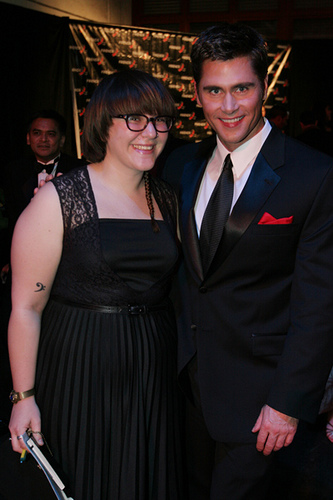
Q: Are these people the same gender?
A: No, they are both male and female.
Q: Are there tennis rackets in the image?
A: No, there are no tennis rackets.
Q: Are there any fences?
A: No, there are no fences.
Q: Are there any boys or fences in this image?
A: No, there are no fences or boys.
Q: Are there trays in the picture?
A: No, there are no trays.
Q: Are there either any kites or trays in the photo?
A: No, there are no trays or kites.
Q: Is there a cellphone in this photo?
A: No, there are no cell phones.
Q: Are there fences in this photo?
A: No, there are no fences.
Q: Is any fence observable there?
A: No, there are no fences.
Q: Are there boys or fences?
A: No, there are no fences or boys.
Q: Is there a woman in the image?
A: Yes, there is a woman.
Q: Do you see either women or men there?
A: Yes, there is a woman.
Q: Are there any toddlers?
A: No, there are no toddlers.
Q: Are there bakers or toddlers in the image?
A: No, there are no toddlers or bakers.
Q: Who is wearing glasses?
A: The woman is wearing glasses.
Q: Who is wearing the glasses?
A: The woman is wearing glasses.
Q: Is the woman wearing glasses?
A: Yes, the woman is wearing glasses.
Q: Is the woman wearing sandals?
A: No, the woman is wearing glasses.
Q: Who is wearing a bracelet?
A: The woman is wearing a bracelet.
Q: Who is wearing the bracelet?
A: The woman is wearing a bracelet.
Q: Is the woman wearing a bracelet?
A: Yes, the woman is wearing a bracelet.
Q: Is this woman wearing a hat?
A: No, the woman is wearing a bracelet.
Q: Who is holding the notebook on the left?
A: The woman is holding the notebook.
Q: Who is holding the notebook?
A: The woman is holding the notebook.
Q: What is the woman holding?
A: The woman is holding the notebook.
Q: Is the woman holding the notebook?
A: Yes, the woman is holding the notebook.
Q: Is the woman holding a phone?
A: No, the woman is holding the notebook.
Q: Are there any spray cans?
A: No, there are no spray cans.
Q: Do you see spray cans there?
A: No, there are no spray cans.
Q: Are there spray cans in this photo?
A: No, there are no spray cans.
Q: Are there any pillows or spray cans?
A: No, there are no spray cans or pillows.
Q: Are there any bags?
A: No, there are no bags.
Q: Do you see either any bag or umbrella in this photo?
A: No, there are no bags or umbrellas.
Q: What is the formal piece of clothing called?
A: The clothing item is a dress.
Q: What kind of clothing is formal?
A: The clothing is a dress.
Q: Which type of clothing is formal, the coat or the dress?
A: The dress is formal.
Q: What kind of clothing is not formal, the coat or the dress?
A: The coat is not formal.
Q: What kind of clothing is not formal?
A: The clothing is a coat.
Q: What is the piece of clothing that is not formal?
A: The clothing item is a coat.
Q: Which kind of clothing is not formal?
A: The clothing is a coat.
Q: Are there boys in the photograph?
A: No, there are no boys.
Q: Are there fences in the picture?
A: No, there are no fences.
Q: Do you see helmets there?
A: No, there are no helmets.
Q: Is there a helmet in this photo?
A: No, there are no helmets.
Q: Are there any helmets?
A: No, there are no helmets.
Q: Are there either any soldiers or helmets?
A: No, there are no helmets or soldiers.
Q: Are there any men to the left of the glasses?
A: Yes, there is a man to the left of the glasses.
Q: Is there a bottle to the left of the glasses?
A: No, there is a man to the left of the glasses.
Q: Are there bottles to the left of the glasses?
A: No, there is a man to the left of the glasses.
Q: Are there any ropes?
A: No, there are no ropes.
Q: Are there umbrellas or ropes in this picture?
A: No, there are no ropes or umbrellas.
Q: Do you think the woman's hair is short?
A: Yes, the hair is short.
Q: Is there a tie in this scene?
A: Yes, there is a tie.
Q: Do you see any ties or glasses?
A: Yes, there is a tie.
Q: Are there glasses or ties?
A: Yes, there is a tie.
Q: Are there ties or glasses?
A: Yes, there is a tie.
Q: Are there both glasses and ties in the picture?
A: Yes, there are both a tie and glasses.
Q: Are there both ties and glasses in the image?
A: Yes, there are both a tie and glasses.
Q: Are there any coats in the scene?
A: Yes, there is a coat.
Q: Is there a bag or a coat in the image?
A: Yes, there is a coat.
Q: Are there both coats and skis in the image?
A: No, there is a coat but no skis.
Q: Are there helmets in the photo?
A: No, there are no helmets.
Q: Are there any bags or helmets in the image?
A: No, there are no helmets or bags.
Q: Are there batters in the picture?
A: No, there are no batters.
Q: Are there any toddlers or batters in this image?
A: No, there are no batters or toddlers.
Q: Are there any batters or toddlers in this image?
A: No, there are no batters or toddlers.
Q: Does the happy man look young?
A: Yes, the man is young.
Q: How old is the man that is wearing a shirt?
A: The man is young.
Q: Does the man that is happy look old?
A: No, the man is young.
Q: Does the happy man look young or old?
A: The man is young.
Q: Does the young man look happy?
A: Yes, the man is happy.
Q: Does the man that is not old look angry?
A: No, the man is happy.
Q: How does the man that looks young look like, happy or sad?
A: The man is happy.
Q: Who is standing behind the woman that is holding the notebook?
A: The man is standing behind the woman.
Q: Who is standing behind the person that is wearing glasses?
A: The man is standing behind the woman.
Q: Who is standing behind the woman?
A: The man is standing behind the woman.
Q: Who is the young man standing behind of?
A: The man is standing behind the woman.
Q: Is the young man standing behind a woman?
A: Yes, the man is standing behind a woman.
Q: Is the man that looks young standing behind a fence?
A: No, the man is standing behind a woman.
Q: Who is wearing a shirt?
A: The man is wearing a shirt.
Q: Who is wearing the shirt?
A: The man is wearing a shirt.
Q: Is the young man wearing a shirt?
A: Yes, the man is wearing a shirt.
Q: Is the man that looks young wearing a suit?
A: No, the man is wearing a shirt.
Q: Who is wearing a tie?
A: The man is wearing a tie.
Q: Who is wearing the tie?
A: The man is wearing a tie.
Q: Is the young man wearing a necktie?
A: Yes, the man is wearing a necktie.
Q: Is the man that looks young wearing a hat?
A: No, the man is wearing a necktie.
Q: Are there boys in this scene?
A: No, there are no boys.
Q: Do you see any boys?
A: No, there are no boys.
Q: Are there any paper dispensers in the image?
A: No, there are no paper dispensers.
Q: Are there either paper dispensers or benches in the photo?
A: No, there are no paper dispensers or benches.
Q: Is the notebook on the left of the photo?
A: Yes, the notebook is on the left of the image.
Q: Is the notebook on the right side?
A: No, the notebook is on the left of the image.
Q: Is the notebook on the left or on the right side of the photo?
A: The notebook is on the left of the image.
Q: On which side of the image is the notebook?
A: The notebook is on the left of the image.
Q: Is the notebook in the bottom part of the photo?
A: Yes, the notebook is in the bottom of the image.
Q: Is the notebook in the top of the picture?
A: No, the notebook is in the bottom of the image.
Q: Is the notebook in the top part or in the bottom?
A: The notebook is in the bottom of the image.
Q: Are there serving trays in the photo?
A: No, there are no serving trays.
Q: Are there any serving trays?
A: No, there are no serving trays.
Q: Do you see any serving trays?
A: No, there are no serving trays.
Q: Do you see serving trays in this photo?
A: No, there are no serving trays.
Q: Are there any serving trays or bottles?
A: No, there are no serving trays or bottles.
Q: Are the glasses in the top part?
A: Yes, the glasses are in the top of the image.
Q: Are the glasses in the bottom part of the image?
A: No, the glasses are in the top of the image.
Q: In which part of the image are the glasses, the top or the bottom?
A: The glasses are in the top of the image.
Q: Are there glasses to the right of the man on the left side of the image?
A: Yes, there are glasses to the right of the man.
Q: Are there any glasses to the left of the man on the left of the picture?
A: No, the glasses are to the right of the man.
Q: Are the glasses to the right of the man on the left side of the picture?
A: Yes, the glasses are to the right of the man.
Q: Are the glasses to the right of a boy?
A: No, the glasses are to the right of the man.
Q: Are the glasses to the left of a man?
A: No, the glasses are to the right of a man.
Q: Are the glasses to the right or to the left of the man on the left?
A: The glasses are to the right of the man.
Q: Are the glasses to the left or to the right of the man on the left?
A: The glasses are to the right of the man.